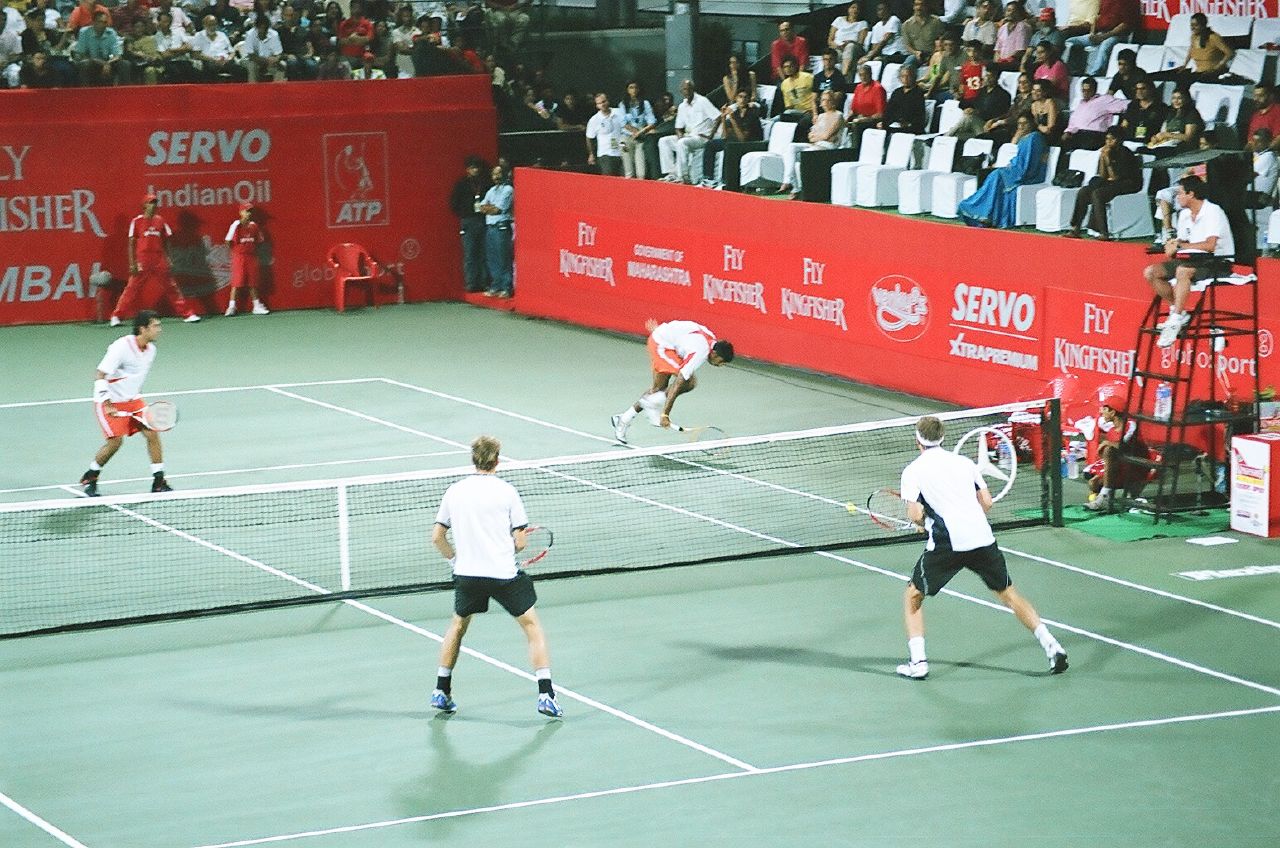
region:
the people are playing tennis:
[98, 94, 1228, 810]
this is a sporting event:
[54, 159, 1078, 839]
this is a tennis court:
[533, 569, 946, 817]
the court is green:
[544, 529, 928, 806]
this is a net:
[62, 364, 632, 689]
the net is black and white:
[65, 499, 361, 674]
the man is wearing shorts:
[402, 382, 639, 711]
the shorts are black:
[405, 507, 591, 671]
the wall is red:
[128, 108, 442, 294]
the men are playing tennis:
[80, 309, 1071, 720]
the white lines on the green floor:
[3, 298, 1275, 839]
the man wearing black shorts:
[433, 435, 557, 716]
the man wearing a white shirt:
[426, 434, 563, 719]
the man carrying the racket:
[427, 437, 558, 722]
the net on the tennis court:
[3, 298, 1275, 837]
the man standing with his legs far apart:
[107, 196, 200, 327]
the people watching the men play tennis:
[0, 8, 1276, 843]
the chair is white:
[830, 125, 886, 203]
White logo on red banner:
[554, 211, 619, 287]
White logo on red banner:
[621, 234, 692, 287]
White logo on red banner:
[696, 242, 767, 315]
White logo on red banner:
[775, 253, 849, 327]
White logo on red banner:
[863, 268, 928, 341]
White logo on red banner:
[947, 272, 1031, 363]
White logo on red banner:
[316, 122, 396, 229]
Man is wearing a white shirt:
[429, 466, 529, 575]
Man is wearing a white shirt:
[901, 444, 994, 553]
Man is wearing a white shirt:
[656, 311, 710, 382]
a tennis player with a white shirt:
[435, 437, 555, 722]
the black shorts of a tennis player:
[908, 541, 1014, 603]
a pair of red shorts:
[95, 395, 149, 438]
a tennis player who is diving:
[608, 315, 736, 455]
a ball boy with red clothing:
[217, 201, 271, 316]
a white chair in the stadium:
[830, 128, 888, 199]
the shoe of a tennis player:
[535, 691, 562, 722]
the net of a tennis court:
[0, 392, 1066, 640]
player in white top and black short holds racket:
[431, 431, 566, 721]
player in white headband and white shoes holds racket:
[897, 418, 1068, 679]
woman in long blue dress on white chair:
[952, 113, 1041, 226]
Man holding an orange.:
[897, 373, 1056, 645]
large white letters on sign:
[948, 280, 1043, 327]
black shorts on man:
[907, 549, 1009, 605]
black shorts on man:
[456, 573, 545, 622]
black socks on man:
[434, 668, 552, 691]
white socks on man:
[909, 627, 1060, 650]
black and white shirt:
[906, 448, 997, 552]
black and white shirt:
[426, 476, 543, 605]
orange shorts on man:
[90, 399, 152, 433]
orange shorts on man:
[648, 337, 686, 373]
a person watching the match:
[1115, 170, 1146, 223]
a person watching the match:
[1071, 29, 1124, 175]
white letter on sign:
[143, 132, 177, 170]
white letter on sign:
[165, 123, 196, 183]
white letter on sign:
[240, 121, 283, 168]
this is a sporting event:
[111, 49, 1217, 776]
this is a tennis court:
[62, 99, 1078, 735]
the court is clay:
[78, 238, 789, 826]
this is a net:
[171, 395, 633, 707]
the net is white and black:
[51, 428, 473, 738]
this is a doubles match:
[54, 203, 1140, 771]